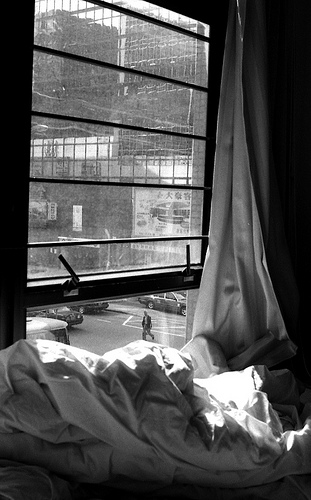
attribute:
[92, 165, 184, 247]
pane — white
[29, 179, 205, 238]
pane — white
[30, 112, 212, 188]
pane — white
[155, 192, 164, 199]
writing — asian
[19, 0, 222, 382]
window — open, opened, white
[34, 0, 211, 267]
wall — white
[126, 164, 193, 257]
wall — white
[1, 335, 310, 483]
blanket — crumpled, white, wrinkled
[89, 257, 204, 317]
car — parked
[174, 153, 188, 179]
pane — white